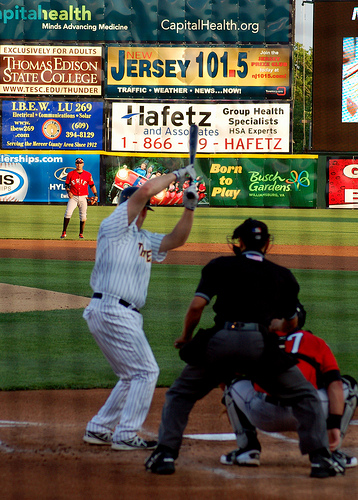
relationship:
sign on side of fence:
[99, 152, 319, 206] [211, 455, 269, 485]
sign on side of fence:
[99, 152, 319, 206] [3, 149, 355, 212]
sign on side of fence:
[99, 152, 319, 206] [0, 1, 356, 208]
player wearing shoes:
[64, 251, 203, 470] [111, 435, 158, 453]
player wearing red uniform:
[219, 320, 354, 469] [247, 330, 340, 393]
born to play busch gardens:
[56, 465, 120, 500] [191, 153, 323, 211]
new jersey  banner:
[60, 255, 109, 328] [107, 44, 291, 101]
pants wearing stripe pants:
[74, 297, 191, 440] [74, 297, 191, 440]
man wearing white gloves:
[55, 161, 202, 454] [171, 161, 208, 211]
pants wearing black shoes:
[74, 297, 191, 440] [141, 449, 175, 475]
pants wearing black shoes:
[74, 297, 191, 440] [307, 454, 345, 478]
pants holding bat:
[74, 297, 191, 440] [187, 124, 198, 199]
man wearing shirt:
[90, 161, 202, 447] [64, 161, 170, 315]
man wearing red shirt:
[50, 151, 99, 245] [60, 169, 99, 197]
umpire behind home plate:
[142, 216, 347, 478] [185, 430, 236, 444]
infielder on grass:
[66, 159, 88, 231] [7, 210, 47, 224]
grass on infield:
[1, 203, 356, 390] [17, 250, 356, 401]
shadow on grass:
[165, 213, 357, 222] [1, 203, 356, 390]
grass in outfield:
[1, 203, 356, 390] [6, 188, 356, 260]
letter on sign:
[109, 47, 125, 83] [106, 40, 299, 102]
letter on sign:
[125, 56, 138, 85] [102, 45, 287, 97]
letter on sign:
[176, 53, 196, 84] [106, 40, 299, 102]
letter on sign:
[177, 56, 192, 81] [103, 90, 305, 162]